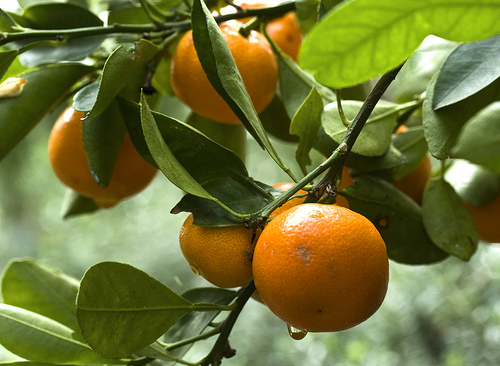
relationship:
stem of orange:
[240, 21, 257, 39] [172, 11, 336, 140]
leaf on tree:
[138, 90, 279, 227] [32, 33, 490, 361]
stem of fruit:
[312, 154, 346, 199] [229, 202, 398, 337]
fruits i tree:
[69, 97, 400, 322] [32, 33, 490, 361]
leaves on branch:
[4, 21, 145, 98] [4, 16, 274, 38]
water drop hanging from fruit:
[286, 322, 312, 343] [250, 202, 389, 333]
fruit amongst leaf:
[250, 202, 389, 333] [138, 90, 279, 227]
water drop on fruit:
[286, 322, 312, 343] [250, 202, 389, 333]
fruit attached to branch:
[169, 17, 277, 125] [4, 16, 274, 38]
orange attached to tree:
[172, 11, 336, 140] [32, 33, 490, 361]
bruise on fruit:
[291, 222, 324, 266] [250, 202, 389, 333]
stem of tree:
[312, 154, 346, 199] [32, 33, 490, 361]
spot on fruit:
[307, 299, 330, 325] [250, 202, 389, 333]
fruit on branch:
[250, 202, 389, 333] [4, 16, 274, 38]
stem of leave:
[312, 154, 346, 199] [76, 18, 196, 47]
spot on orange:
[307, 299, 330, 325] [172, 11, 336, 140]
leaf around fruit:
[138, 90, 279, 227] [250, 202, 389, 333]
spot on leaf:
[185, 145, 219, 165] [138, 111, 271, 217]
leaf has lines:
[138, 111, 271, 217] [205, 173, 250, 215]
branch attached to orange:
[4, 16, 274, 38] [172, 11, 336, 140]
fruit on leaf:
[250, 202, 389, 333] [138, 111, 271, 217]